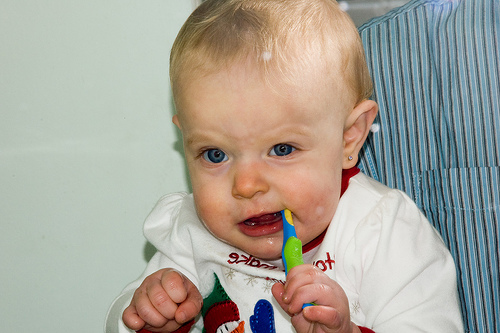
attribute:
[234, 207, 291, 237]
mouth — open, baby's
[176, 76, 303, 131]
forehead — white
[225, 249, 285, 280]
writing — red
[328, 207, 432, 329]
cloth — white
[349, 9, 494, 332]
cover — blue, striped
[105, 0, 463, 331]
baby — Dressed in white , teeth brushing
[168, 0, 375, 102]
hair — Blonde 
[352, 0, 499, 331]
shirt — blue, striped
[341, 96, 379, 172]
ear — pierced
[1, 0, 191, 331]
wall — white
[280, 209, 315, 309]
object — green, yellow, blue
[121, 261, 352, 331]
two hands — Balled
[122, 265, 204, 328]
baby's hand — closed